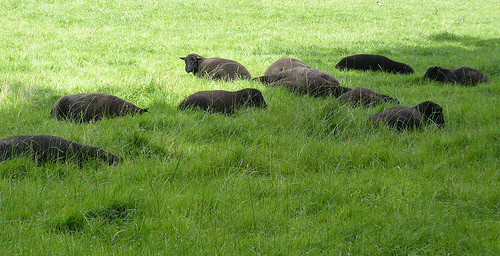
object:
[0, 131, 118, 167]
animal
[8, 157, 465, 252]
grass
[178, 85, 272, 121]
cow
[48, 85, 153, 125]
cow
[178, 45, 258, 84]
cow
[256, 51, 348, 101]
cow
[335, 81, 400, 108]
cow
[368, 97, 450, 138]
cow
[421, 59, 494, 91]
cow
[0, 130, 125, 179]
cow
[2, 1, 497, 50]
grass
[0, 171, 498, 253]
grass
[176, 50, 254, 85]
sheep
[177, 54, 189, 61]
ear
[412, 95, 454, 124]
animal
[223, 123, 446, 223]
grass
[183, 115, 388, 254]
grass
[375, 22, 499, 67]
shadows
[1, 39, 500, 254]
shade'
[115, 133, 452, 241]
grass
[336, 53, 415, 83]
cow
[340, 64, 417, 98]
grass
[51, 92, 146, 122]
animal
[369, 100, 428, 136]
animal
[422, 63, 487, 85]
animal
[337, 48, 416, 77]
animal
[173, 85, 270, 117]
animal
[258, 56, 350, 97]
animal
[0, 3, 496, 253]
grass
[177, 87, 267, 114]
sheep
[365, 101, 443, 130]
sheep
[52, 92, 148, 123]
sheep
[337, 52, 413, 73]
sheep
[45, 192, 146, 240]
area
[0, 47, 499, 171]
animals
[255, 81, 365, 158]
grass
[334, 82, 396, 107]
animal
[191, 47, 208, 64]
tag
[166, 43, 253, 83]
animal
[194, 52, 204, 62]
ear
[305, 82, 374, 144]
grass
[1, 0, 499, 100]
light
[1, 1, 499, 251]
ground